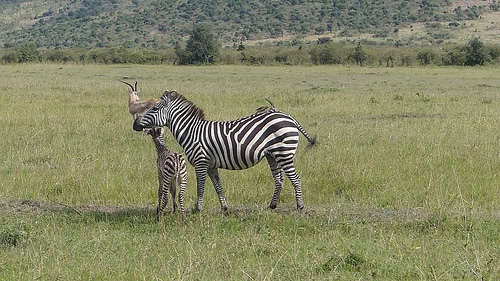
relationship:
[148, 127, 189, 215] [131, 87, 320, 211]
zebra next to zebra